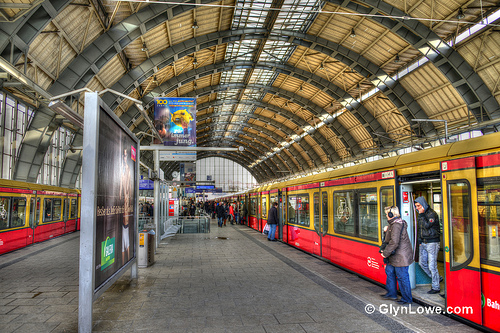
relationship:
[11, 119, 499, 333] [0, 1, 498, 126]
train station has domed ceiling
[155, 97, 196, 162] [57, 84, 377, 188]
sign are in center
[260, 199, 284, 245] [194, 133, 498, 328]
person facing train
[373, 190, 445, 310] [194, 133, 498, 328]
people leaving train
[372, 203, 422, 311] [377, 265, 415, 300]
person wears blue pants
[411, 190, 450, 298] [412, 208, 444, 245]
man wearing black jacket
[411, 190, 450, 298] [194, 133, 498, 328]
men exiting train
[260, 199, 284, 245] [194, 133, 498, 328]
man enters train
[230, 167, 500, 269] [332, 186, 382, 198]
windows has black trimming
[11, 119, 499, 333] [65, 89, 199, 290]
train station has billboards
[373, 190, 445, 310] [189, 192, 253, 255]
people walking alongside  train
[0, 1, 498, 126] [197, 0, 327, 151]
ceiling has windows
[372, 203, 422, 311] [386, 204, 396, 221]
person wears headphones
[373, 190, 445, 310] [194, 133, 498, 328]
two people leaving train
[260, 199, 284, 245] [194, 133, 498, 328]
person getting on train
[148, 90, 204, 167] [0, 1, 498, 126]
sign hangs from ceiling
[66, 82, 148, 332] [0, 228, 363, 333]
sign on floor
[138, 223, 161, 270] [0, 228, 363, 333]
trash can on floor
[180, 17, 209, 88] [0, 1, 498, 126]
lights on ceiling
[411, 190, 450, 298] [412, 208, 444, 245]
person wears eather jacket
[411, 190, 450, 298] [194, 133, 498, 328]
man getting off train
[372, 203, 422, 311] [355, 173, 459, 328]
woman got off train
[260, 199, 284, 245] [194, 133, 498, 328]
man get on train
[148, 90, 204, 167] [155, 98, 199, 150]
poster of movie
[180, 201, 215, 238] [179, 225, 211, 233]
stairs lead to lower level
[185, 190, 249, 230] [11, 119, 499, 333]
people in train station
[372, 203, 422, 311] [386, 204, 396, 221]
woman wears earphones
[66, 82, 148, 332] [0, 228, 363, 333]
sign on platform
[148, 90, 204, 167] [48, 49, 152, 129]
sign hangs from platform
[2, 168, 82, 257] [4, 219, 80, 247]
train on tracks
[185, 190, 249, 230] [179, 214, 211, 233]
people walking on lower level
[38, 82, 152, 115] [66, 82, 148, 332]
lights on sign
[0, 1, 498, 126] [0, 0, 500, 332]
girders mounted on ceiling of train station